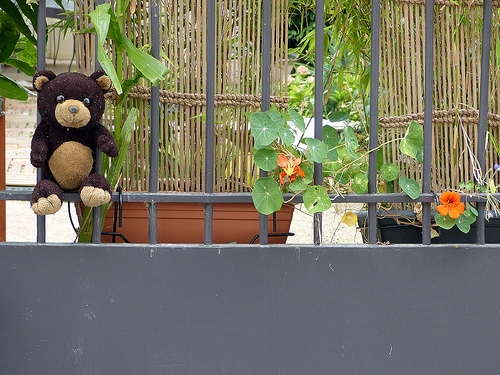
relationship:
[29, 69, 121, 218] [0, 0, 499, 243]
teddy bear hanging on fence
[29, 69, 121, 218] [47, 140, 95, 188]
teddy bear has brown tummy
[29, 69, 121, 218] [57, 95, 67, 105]
teddy bear has eye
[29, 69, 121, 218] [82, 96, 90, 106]
teddy bear has eye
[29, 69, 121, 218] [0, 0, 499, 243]
teddy bear sitting on fence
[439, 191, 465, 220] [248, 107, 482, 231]
flower on plant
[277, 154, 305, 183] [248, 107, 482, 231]
flower on plant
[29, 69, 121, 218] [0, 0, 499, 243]
teddy bear on fence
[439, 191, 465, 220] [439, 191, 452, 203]
flower has orange petal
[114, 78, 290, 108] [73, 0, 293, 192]
rope attached to wood sticks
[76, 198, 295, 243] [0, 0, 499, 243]
clay pot behind fence